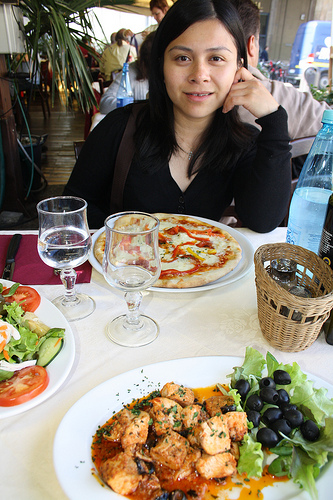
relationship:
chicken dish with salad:
[91, 371, 255, 498] [215, 340, 331, 497]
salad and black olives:
[215, 340, 331, 497] [217, 365, 324, 450]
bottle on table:
[283, 99, 331, 242] [46, 362, 328, 499]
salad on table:
[2, 284, 48, 390] [149, 293, 258, 351]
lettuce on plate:
[232, 360, 285, 459] [23, 290, 103, 370]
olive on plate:
[272, 370, 291, 386] [48, 361, 332, 499]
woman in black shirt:
[61, 0, 293, 231] [54, 93, 295, 237]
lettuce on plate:
[250, 365, 308, 401] [48, 361, 332, 499]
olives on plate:
[235, 383, 297, 441] [48, 361, 332, 499]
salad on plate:
[1, 322, 60, 374] [0, 274, 78, 420]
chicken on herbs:
[103, 377, 246, 493] [225, 347, 331, 498]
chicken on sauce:
[103, 377, 246, 493] [97, 427, 292, 497]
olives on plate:
[233, 369, 331, 455] [45, 342, 323, 492]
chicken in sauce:
[103, 377, 246, 493] [92, 383, 249, 499]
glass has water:
[33, 194, 96, 321] [32, 224, 95, 274]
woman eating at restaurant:
[61, 0, 293, 231] [1, 0, 332, 499]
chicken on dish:
[103, 377, 246, 493] [104, 197, 260, 298]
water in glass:
[30, 221, 98, 270] [29, 194, 102, 327]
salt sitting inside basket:
[270, 256, 300, 302] [252, 235, 332, 361]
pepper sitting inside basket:
[282, 283, 317, 320] [252, 235, 332, 361]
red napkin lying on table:
[1, 234, 91, 284] [6, 219, 322, 498]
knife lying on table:
[1, 231, 21, 279] [6, 219, 322, 498]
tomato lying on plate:
[0, 365, 48, 405] [0, 274, 78, 420]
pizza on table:
[94, 212, 239, 287] [71, 284, 264, 353]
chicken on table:
[103, 377, 246, 493] [6, 219, 322, 498]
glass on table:
[33, 194, 96, 321] [180, 310, 233, 343]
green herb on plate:
[114, 368, 161, 407] [48, 361, 332, 499]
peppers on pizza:
[169, 224, 201, 262] [162, 217, 231, 285]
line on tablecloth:
[78, 340, 121, 369] [6, 221, 329, 497]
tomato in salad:
[1, 285, 39, 314] [0, 277, 65, 405]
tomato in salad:
[0, 365, 48, 405] [0, 277, 65, 405]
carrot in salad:
[0, 341, 11, 361] [0, 277, 65, 405]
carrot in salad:
[0, 324, 8, 340] [0, 277, 65, 405]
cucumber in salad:
[36, 333, 64, 366] [0, 277, 65, 405]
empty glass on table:
[102, 210, 160, 347] [6, 219, 322, 498]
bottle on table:
[283, 99, 331, 242] [4, 215, 323, 410]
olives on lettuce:
[270, 368, 293, 383] [222, 348, 328, 499]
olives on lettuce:
[259, 372, 274, 390] [222, 348, 328, 499]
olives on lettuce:
[236, 373, 247, 395] [222, 348, 328, 499]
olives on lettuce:
[257, 385, 277, 402] [222, 348, 328, 499]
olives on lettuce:
[248, 390, 260, 408] [222, 348, 328, 499]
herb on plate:
[238, 348, 332, 480] [48, 361, 332, 499]